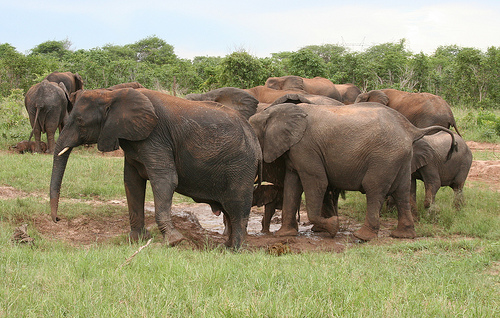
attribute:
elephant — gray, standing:
[52, 88, 263, 251]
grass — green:
[0, 104, 499, 317]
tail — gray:
[254, 131, 264, 199]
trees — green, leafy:
[1, 33, 500, 110]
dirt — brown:
[0, 137, 499, 255]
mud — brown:
[1, 183, 408, 256]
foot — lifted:
[163, 225, 185, 246]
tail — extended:
[412, 124, 460, 163]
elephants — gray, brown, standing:
[25, 71, 473, 252]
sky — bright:
[0, 0, 499, 66]